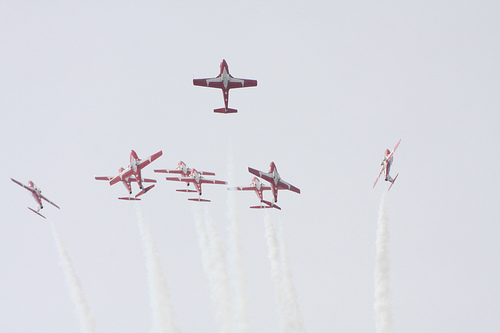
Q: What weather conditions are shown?
A: It is clear.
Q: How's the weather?
A: It is clear.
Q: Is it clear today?
A: Yes, it is clear.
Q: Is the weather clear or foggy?
A: It is clear.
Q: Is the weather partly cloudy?
A: No, it is clear.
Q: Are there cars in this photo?
A: No, there are no cars.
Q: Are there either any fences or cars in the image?
A: No, there are no cars or fences.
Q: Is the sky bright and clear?
A: Yes, the sky is bright and clear.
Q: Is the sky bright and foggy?
A: No, the sky is bright but clear.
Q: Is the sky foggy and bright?
A: No, the sky is bright but clear.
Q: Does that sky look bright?
A: Yes, the sky is bright.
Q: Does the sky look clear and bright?
A: Yes, the sky is clear and bright.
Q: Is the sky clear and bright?
A: Yes, the sky is clear and bright.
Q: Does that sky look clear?
A: Yes, the sky is clear.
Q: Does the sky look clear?
A: Yes, the sky is clear.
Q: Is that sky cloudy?
A: No, the sky is clear.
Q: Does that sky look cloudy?
A: No, the sky is clear.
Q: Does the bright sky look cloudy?
A: No, the sky is clear.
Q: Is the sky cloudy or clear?
A: The sky is clear.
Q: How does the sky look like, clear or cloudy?
A: The sky is clear.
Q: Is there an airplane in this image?
A: Yes, there is an airplane.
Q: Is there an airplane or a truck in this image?
A: Yes, there is an airplane.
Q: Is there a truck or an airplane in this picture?
A: Yes, there is an airplane.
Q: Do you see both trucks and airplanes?
A: No, there is an airplane but no trucks.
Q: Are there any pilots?
A: No, there are no pilots.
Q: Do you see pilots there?
A: No, there are no pilots.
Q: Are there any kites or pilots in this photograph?
A: No, there are no pilots or kites.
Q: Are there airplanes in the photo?
A: Yes, there are airplanes.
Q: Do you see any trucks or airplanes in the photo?
A: Yes, there are airplanes.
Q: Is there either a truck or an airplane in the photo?
A: Yes, there are airplanes.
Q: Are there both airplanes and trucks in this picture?
A: No, there are airplanes but no trucks.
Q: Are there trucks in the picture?
A: No, there are no trucks.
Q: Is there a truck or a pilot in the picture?
A: No, there are no trucks or pilots.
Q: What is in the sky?
A: The airplanes are in the sky.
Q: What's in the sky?
A: The airplanes are in the sky.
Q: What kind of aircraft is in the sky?
A: The aircraft is airplanes.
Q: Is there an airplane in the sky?
A: Yes, there are airplanes in the sky.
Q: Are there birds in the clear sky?
A: No, there are airplanes in the sky.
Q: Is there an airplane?
A: Yes, there is an airplane.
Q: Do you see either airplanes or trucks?
A: Yes, there is an airplane.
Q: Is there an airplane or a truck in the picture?
A: Yes, there is an airplane.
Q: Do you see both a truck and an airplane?
A: No, there is an airplane but no trucks.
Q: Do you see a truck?
A: No, there are no trucks.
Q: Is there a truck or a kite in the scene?
A: No, there are no trucks or kites.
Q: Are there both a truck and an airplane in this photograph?
A: No, there is an airplane but no trucks.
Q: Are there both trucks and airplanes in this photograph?
A: No, there is an airplane but no trucks.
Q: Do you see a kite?
A: No, there are no kites.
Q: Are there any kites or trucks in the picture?
A: No, there are no kites or trucks.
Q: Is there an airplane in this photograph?
A: Yes, there is an airplane.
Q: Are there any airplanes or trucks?
A: Yes, there is an airplane.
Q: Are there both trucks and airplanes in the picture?
A: No, there is an airplane but no trucks.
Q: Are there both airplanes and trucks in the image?
A: No, there is an airplane but no trucks.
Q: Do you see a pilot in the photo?
A: No, there are no pilots.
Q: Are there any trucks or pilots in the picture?
A: No, there are no pilots or trucks.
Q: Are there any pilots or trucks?
A: No, there are no pilots or trucks.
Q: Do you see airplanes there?
A: Yes, there is an airplane.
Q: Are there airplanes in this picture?
A: Yes, there is an airplane.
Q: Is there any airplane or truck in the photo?
A: Yes, there is an airplane.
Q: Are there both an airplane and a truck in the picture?
A: No, there is an airplane but no trucks.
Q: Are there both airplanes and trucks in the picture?
A: No, there is an airplane but no trucks.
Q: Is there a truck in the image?
A: No, there are no trucks.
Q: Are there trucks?
A: No, there are no trucks.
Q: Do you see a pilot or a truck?
A: No, there are no trucks or pilots.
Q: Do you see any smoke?
A: Yes, there is smoke.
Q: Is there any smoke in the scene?
A: Yes, there is smoke.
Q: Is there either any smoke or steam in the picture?
A: Yes, there is smoke.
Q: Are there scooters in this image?
A: No, there are no scooters.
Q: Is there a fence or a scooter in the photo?
A: No, there are no scooters or fences.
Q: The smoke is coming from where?
A: The smoke is coming from the airplane.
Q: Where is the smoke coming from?
A: The smoke is coming from the airplane.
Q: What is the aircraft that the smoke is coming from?
A: The aircraft is an airplane.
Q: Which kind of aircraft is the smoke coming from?
A: The smoke is coming from the airplane.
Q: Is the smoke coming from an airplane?
A: Yes, the smoke is coming from an airplane.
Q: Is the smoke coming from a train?
A: No, the smoke is coming from an airplane.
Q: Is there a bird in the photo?
A: No, there are no birds.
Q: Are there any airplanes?
A: Yes, there is an airplane.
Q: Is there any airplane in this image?
A: Yes, there is an airplane.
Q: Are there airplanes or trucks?
A: Yes, there is an airplane.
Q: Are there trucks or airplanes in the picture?
A: Yes, there is an airplane.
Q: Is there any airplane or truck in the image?
A: Yes, there is an airplane.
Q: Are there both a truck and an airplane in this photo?
A: No, there is an airplane but no trucks.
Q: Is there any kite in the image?
A: No, there are no kites.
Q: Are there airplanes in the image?
A: Yes, there is an airplane.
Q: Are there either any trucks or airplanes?
A: Yes, there is an airplane.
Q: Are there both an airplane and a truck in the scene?
A: No, there is an airplane but no trucks.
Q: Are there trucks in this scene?
A: No, there are no trucks.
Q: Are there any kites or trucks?
A: No, there are no trucks or kites.